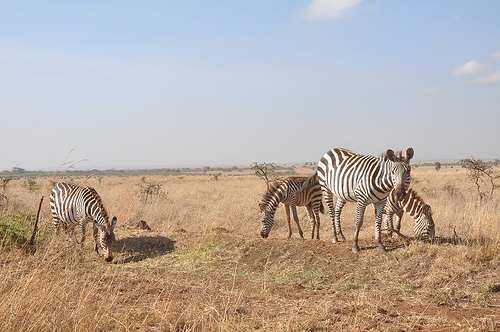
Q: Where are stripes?
A: On zebra.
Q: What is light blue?
A: The sky.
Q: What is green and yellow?
A: Grass.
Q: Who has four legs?
A: One zebra.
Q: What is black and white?
A: The zebra.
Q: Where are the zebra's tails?
A: On their backs.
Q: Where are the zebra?
A: On a field.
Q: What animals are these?
A: Zebra.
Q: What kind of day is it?
A: Sunny.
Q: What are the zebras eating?
A: Grass.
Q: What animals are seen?
A: Zebras.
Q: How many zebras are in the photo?
A: Four.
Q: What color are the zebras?
A: Black and White.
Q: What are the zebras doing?
A: Grazing.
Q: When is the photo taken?
A: Daytime.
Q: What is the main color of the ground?
A: Brown.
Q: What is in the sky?
A: Clouds.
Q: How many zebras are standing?
A: Four.